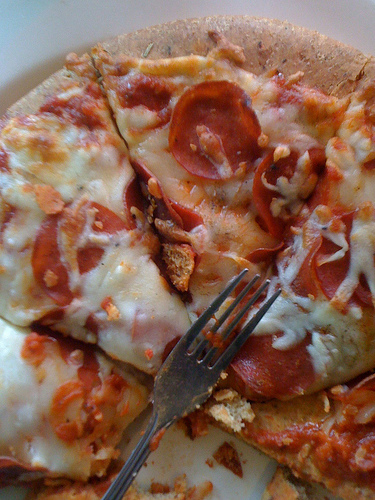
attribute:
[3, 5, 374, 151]
bread — part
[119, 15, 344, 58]
bread — part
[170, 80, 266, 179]
pepperoni — red, circular, piece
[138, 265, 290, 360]
spoon — part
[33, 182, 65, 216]
crumb — crust, light, brown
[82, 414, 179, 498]
handle — part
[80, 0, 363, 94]
crust — light, brown, crumb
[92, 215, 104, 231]
crumb — crust, light, brown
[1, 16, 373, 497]
crust crumb — brown, light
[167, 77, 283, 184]
pepperoni — circular, red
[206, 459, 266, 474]
crunch — part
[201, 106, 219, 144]
tomato — part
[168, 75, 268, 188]
pepperoni — piece, red, circular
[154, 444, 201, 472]
plate — white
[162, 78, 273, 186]
pepperoni — circular, red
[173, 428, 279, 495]
surface — part